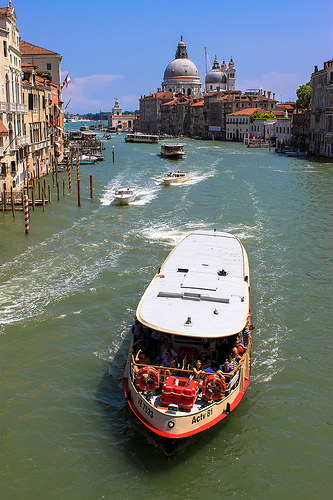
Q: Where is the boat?
A: In the river.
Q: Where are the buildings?
A: Next to the water.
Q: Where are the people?
A: Sitting in the front.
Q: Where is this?
A: In Italy.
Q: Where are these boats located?
A: Venice.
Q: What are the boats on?
A: Water.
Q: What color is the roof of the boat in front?
A: White.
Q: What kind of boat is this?
A: Tour boat.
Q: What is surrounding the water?
A: Buildings.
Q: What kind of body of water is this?
A: River.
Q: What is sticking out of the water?
A: Wooden poles.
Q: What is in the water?
A: Boats.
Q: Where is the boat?
A: A canal.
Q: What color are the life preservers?
A: Orange.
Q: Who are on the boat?
A: Passengers.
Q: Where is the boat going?
A: Down the canal.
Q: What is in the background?
A: A city.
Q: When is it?
A: Daytime.